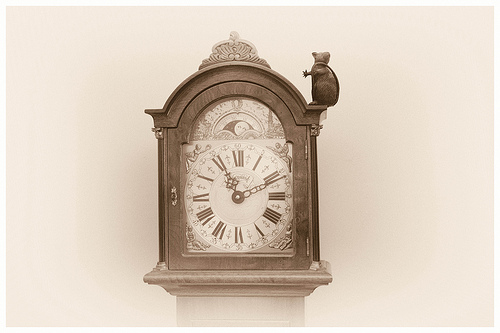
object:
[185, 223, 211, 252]
drawing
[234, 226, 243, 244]
roman numeral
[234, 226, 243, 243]
six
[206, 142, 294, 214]
11:11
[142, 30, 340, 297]
pink marker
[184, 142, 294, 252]
clock face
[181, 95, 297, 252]
glass door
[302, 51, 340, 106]
mouse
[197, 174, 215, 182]
numeral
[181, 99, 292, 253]
analogue clock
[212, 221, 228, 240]
roman numerals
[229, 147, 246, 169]
xii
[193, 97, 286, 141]
drawing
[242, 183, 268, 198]
arm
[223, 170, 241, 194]
arm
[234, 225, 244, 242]
vi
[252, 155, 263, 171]
number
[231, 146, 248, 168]
roman numeral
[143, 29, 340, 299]
clock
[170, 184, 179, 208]
knob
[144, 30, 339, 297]
tower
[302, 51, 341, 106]
animal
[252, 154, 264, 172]
roman numeral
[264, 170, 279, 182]
roman numeral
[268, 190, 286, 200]
roman numeral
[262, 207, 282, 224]
roman numeral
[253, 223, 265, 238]
roman numeral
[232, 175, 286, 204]
hand